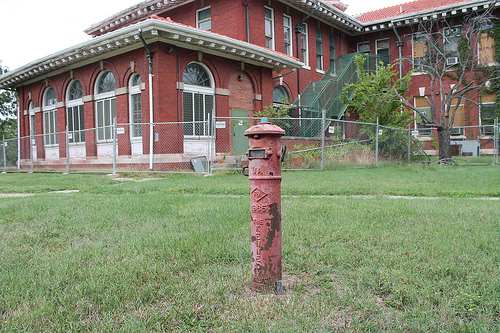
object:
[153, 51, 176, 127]
bricks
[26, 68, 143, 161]
doors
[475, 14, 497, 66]
window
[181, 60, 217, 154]
door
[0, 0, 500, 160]
house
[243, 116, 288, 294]
bollard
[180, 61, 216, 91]
tops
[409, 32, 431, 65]
plywood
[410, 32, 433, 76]
windows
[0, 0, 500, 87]
roof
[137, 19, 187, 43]
effects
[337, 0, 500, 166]
bushes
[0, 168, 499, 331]
area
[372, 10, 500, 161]
trees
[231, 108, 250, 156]
door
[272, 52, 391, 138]
staircase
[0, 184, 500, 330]
grass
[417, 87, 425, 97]
sign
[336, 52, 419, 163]
tree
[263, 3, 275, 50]
window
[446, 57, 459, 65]
unit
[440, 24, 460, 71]
window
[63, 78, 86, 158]
window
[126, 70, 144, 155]
window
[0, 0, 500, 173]
building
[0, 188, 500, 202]
path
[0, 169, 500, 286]
yard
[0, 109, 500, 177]
fence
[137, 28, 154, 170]
drain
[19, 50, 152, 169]
wall